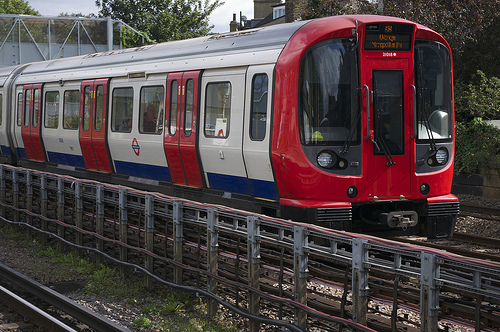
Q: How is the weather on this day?
A: It is cloudy.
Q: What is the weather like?
A: It is cloudy.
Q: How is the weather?
A: It is cloudy.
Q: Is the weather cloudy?
A: Yes, it is cloudy.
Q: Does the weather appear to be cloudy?
A: Yes, it is cloudy.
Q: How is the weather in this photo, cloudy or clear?
A: It is cloudy.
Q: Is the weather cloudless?
A: No, it is cloudy.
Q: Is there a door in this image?
A: Yes, there is a door.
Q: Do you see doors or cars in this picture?
A: Yes, there is a door.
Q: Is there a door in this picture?
A: Yes, there is a door.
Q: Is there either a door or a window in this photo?
A: Yes, there is a door.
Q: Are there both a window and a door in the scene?
A: Yes, there are both a door and a window.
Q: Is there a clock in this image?
A: No, there are no clocks.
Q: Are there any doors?
A: Yes, there is a door.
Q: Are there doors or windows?
A: Yes, there is a door.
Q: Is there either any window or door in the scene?
A: Yes, there is a door.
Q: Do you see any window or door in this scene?
A: Yes, there is a door.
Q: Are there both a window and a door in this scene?
A: Yes, there are both a door and a window.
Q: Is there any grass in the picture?
A: Yes, there is grass.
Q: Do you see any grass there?
A: Yes, there is grass.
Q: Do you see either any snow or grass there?
A: Yes, there is grass.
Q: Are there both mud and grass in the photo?
A: No, there is grass but no mud.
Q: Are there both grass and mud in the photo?
A: No, there is grass but no mud.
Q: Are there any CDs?
A: No, there are no cds.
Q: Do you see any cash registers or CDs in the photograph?
A: No, there are no CDs or cash registers.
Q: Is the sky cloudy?
A: Yes, the sky is cloudy.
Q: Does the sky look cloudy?
A: Yes, the sky is cloudy.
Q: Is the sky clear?
A: No, the sky is cloudy.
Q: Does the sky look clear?
A: No, the sky is cloudy.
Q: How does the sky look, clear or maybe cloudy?
A: The sky is cloudy.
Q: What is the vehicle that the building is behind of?
A: The vehicle is a train.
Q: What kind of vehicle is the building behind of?
A: The building is behind the train.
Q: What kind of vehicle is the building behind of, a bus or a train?
A: The building is behind a train.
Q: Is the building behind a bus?
A: No, the building is behind the train.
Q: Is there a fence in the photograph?
A: Yes, there is a fence.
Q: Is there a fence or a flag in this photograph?
A: Yes, there is a fence.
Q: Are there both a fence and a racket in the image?
A: No, there is a fence but no rackets.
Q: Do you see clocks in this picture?
A: No, there are no clocks.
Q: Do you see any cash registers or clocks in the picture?
A: No, there are no clocks or cash registers.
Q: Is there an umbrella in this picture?
A: No, there are no umbrellas.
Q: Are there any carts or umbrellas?
A: No, there are no umbrellas or carts.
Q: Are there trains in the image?
A: Yes, there is a train.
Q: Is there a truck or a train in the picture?
A: Yes, there is a train.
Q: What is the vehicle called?
A: The vehicle is a train.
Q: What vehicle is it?
A: The vehicle is a train.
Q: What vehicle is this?
A: That is a train.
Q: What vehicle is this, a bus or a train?
A: That is a train.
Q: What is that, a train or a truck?
A: That is a train.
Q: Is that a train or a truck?
A: That is a train.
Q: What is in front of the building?
A: The train is in front of the building.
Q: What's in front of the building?
A: The train is in front of the building.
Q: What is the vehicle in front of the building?
A: The vehicle is a train.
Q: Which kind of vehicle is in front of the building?
A: The vehicle is a train.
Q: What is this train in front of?
A: The train is in front of the building.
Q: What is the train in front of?
A: The train is in front of the building.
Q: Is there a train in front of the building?
A: Yes, there is a train in front of the building.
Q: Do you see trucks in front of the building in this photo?
A: No, there is a train in front of the building.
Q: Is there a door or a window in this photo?
A: Yes, there is a door.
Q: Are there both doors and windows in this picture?
A: Yes, there are both a door and windows.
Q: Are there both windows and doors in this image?
A: Yes, there are both a door and windows.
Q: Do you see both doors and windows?
A: Yes, there are both a door and windows.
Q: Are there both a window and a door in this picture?
A: Yes, there are both a door and a window.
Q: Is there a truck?
A: No, there are no trucks.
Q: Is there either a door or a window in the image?
A: Yes, there is a window.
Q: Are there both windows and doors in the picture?
A: Yes, there are both a window and a door.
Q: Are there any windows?
A: Yes, there is a window.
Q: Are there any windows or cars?
A: Yes, there is a window.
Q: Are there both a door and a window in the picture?
A: Yes, there are both a window and a door.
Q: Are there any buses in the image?
A: No, there are no buses.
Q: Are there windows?
A: Yes, there is a window.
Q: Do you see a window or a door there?
A: Yes, there is a window.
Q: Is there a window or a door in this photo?
A: Yes, there is a window.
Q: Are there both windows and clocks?
A: No, there is a window but no clocks.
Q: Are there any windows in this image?
A: Yes, there is a window.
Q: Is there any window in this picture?
A: Yes, there is a window.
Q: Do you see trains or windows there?
A: Yes, there is a window.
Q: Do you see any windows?
A: Yes, there is a window.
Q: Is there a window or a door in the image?
A: Yes, there is a window.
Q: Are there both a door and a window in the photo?
A: Yes, there are both a window and a door.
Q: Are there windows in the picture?
A: Yes, there is a window.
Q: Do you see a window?
A: Yes, there is a window.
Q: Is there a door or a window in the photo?
A: Yes, there is a window.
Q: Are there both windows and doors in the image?
A: Yes, there are both a window and doors.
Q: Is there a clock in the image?
A: No, there are no clocks.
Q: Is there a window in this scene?
A: Yes, there is a window.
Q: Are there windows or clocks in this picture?
A: Yes, there is a window.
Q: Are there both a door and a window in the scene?
A: Yes, there are both a window and a door.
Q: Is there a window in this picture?
A: Yes, there is a window.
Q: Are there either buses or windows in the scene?
A: Yes, there is a window.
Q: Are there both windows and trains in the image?
A: Yes, there are both a window and a train.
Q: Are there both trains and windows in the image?
A: Yes, there are both a window and a train.